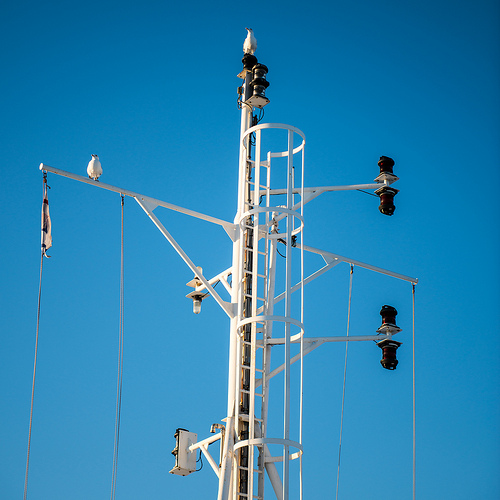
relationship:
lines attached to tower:
[411, 281, 418, 495] [34, 21, 428, 498]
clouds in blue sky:
[0, 0, 500, 500] [0, 0, 500, 500]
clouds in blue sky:
[26, 56, 446, 178] [0, 0, 500, 500]